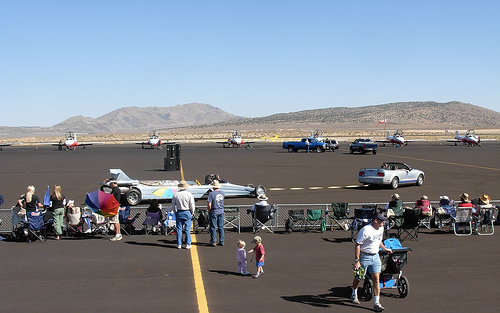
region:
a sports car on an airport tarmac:
[353, 155, 433, 195]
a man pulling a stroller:
[340, 208, 412, 305]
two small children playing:
[231, 232, 273, 281]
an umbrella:
[77, 184, 127, 228]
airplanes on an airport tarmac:
[30, 123, 183, 157]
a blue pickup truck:
[277, 131, 334, 158]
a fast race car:
[97, 164, 286, 216]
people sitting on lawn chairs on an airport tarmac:
[388, 191, 492, 241]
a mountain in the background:
[89, 99, 240, 134]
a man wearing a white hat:
[167, 178, 198, 253]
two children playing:
[235, 235, 271, 278]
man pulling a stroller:
[347, 212, 412, 302]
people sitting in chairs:
[385, 192, 497, 235]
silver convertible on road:
[347, 148, 432, 191]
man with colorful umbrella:
[85, 176, 126, 242]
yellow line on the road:
[170, 257, 218, 312]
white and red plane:
[47, 128, 94, 157]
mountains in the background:
[94, 89, 217, 124]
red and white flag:
[370, 113, 388, 131]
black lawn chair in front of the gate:
[285, 198, 305, 231]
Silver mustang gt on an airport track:
[357, 158, 432, 190]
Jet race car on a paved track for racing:
[96, 165, 274, 206]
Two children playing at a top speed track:
[228, 233, 272, 280]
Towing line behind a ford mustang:
[265, 179, 371, 195]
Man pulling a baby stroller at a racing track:
[345, 211, 416, 310]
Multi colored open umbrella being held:
[82, 191, 121, 221]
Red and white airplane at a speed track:
[46, 128, 98, 155]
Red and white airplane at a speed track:
[134, 126, 182, 153]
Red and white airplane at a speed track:
[213, 128, 256, 150]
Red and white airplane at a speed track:
[380, 125, 417, 154]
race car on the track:
[106, 159, 266, 209]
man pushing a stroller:
[333, 232, 431, 279]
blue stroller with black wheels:
[371, 237, 413, 299]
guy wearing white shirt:
[355, 220, 385, 260]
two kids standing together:
[223, 223, 281, 285]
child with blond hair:
[232, 239, 249, 276]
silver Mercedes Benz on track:
[351, 151, 433, 190]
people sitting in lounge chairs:
[407, 188, 489, 229]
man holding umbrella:
[91, 185, 128, 235]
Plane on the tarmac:
[54, 122, 114, 160]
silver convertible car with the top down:
[355, 159, 425, 187]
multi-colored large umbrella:
[84, 188, 121, 217]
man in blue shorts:
[351, 209, 386, 306]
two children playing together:
[235, 235, 266, 280]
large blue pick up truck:
[280, 135, 330, 154]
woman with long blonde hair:
[50, 180, 68, 240]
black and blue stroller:
[383, 236, 412, 297]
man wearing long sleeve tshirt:
[170, 178, 195, 251]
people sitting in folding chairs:
[391, 194, 496, 234]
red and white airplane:
[213, 132, 265, 149]